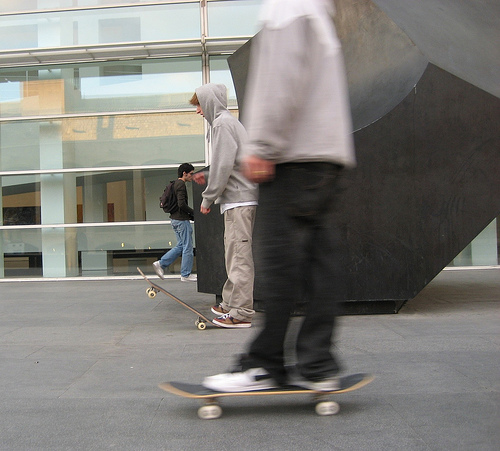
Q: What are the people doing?
A: Skating.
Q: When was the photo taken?
A: Afternoon.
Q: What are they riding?
A: Skateboards.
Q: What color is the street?
A: Black.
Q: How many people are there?
A: Three.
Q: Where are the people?
A: On the street.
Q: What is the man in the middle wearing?
A: A hoodie.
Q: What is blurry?
A: The feet of the guy in the front.